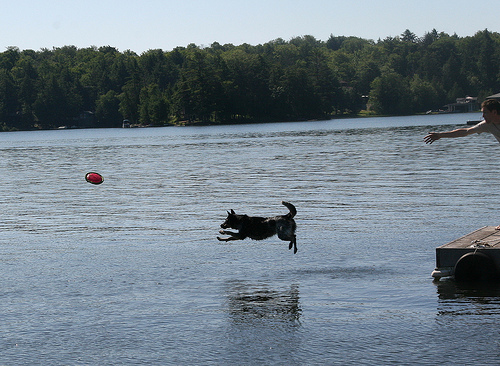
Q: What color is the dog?
A: Black.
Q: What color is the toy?
A: Red.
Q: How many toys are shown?
A: One.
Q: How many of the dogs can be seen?
A: One.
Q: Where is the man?
A: On deck.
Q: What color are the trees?
A: Green.